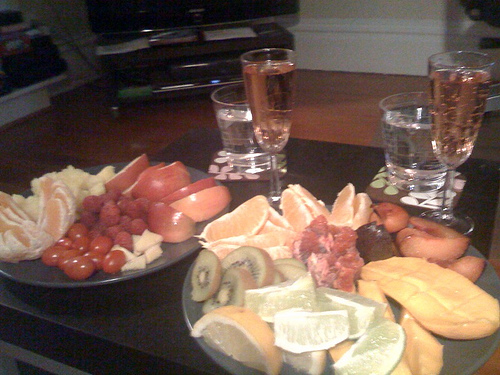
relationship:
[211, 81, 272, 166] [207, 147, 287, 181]
glass sitting on coaster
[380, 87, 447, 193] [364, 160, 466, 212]
glass sitting on coaster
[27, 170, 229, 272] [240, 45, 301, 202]
fruit and wine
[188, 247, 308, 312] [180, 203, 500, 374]
kiwi on fruit plates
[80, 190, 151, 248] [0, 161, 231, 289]
raspberries on fruit plates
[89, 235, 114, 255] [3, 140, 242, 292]
tomatoe on plate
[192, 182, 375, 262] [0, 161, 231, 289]
orange on fruit plates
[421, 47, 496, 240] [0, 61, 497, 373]
champagne glass on table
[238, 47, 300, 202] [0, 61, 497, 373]
champagne glass on table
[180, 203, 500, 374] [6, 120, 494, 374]
fruit plates on table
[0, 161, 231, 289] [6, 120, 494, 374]
fruit plates on table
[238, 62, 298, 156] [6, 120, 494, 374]
champagne on table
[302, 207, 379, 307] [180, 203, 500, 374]
raspberries in center  of fruit plates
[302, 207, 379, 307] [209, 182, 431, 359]
raspberries in center  of fruit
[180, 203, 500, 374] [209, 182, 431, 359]
fruit plates of fruit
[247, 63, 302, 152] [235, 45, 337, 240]
champagne on glass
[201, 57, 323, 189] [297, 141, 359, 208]
water on table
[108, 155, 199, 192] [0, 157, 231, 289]
apple slices on fruit plates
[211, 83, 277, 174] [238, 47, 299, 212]
glass beside champagne glass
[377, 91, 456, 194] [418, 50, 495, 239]
glass beside champagne glass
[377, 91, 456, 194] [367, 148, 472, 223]
glass sitting on napkin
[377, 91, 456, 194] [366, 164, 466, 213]
glass on coaster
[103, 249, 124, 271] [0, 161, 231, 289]
grape on fruit plates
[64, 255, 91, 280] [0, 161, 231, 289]
grape on fruit plates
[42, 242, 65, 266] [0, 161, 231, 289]
grape on fruit plates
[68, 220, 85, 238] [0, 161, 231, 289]
grape on fruit plates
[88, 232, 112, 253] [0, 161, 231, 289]
grape on fruit plates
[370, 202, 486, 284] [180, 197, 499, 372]
peach on fruit plates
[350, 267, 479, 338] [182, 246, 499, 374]
bread on plate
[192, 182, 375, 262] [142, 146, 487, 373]
orange on plate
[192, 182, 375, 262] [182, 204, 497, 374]
orange on plate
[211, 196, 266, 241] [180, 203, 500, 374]
orange on fruit plates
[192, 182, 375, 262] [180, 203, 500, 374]
orange on fruit plates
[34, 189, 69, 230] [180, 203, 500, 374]
orange on fruit plates